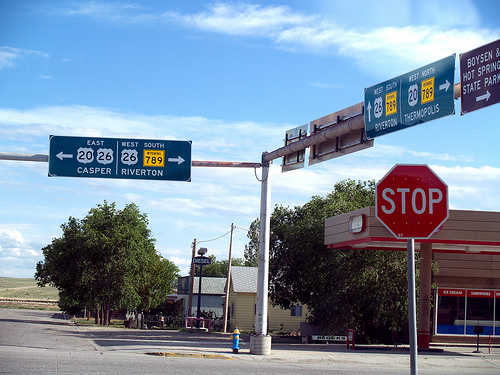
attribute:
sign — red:
[379, 163, 442, 248]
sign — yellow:
[142, 146, 164, 168]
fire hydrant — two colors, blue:
[230, 289, 276, 356]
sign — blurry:
[346, 212, 369, 236]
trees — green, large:
[46, 205, 155, 326]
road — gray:
[17, 308, 207, 366]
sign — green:
[48, 135, 192, 181]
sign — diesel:
[308, 333, 352, 343]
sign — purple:
[458, 42, 498, 105]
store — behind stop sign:
[325, 205, 494, 354]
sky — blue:
[81, 29, 250, 99]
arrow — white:
[166, 154, 188, 165]